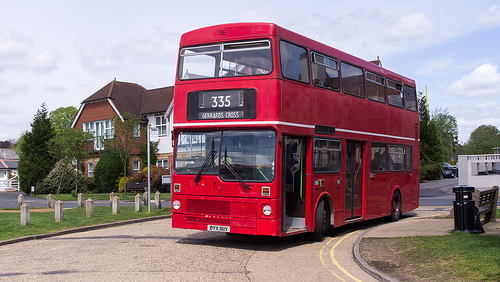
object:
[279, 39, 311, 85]
window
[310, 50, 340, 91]
window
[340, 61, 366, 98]
window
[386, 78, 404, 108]
window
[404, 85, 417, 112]
window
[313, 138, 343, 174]
window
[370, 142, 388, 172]
window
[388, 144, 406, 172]
window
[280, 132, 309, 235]
door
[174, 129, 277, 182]
windshield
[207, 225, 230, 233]
plate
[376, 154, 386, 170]
person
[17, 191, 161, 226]
fence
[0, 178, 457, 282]
road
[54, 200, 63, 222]
post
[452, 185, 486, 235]
receptacle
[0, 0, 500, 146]
sky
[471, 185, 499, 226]
bench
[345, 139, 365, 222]
double door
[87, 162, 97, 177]
window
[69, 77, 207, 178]
building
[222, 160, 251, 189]
windshield wiper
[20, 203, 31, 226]
posts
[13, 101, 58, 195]
trees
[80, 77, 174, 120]
roof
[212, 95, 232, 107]
335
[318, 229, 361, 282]
line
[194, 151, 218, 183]
windhsield wiper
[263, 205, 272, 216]
light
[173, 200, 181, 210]
light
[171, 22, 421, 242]
bus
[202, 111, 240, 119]
text